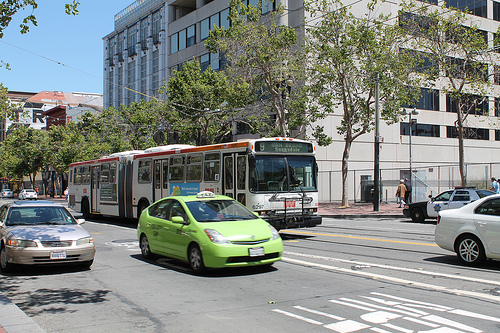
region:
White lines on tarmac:
[334, 293, 450, 326]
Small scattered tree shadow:
[22, 284, 119, 316]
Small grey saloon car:
[2, 203, 99, 272]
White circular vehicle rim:
[453, 235, 483, 264]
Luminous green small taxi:
[158, 193, 285, 281]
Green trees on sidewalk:
[102, 92, 204, 141]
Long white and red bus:
[94, 158, 259, 189]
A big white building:
[391, 128, 459, 165]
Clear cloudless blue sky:
[62, 26, 93, 53]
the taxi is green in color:
[132, 185, 316, 285]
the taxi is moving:
[164, 192, 268, 285]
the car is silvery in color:
[12, 185, 81, 280]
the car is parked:
[10, 185, 97, 290]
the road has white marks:
[344, 282, 425, 331]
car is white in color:
[438, 199, 499, 254]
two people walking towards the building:
[379, 165, 415, 198]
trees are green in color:
[86, 109, 184, 139]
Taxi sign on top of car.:
[199, 186, 218, 202]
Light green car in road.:
[134, 188, 259, 285]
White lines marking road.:
[331, 296, 379, 329]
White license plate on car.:
[246, 247, 266, 254]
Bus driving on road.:
[146, 156, 314, 202]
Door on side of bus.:
[90, 168, 110, 206]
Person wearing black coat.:
[406, 180, 416, 199]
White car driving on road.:
[438, 198, 489, 249]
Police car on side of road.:
[408, 190, 463, 224]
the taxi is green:
[144, 185, 282, 272]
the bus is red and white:
[132, 147, 321, 232]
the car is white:
[435, 201, 498, 268]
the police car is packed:
[401, 186, 481, 216]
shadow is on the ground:
[36, 285, 106, 322]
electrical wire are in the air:
[66, 61, 148, 101]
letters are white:
[315, 275, 460, 332]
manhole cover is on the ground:
[117, 234, 139, 254]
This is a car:
[136, 187, 288, 293]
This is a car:
[428, 191, 490, 241]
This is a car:
[400, 183, 497, 218]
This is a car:
[20, 180, 41, 210]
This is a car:
[2, 175, 27, 211]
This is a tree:
[427, 11, 497, 228]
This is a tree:
[312, 1, 380, 222]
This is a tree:
[230, 18, 312, 174]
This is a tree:
[171, 60, 243, 170]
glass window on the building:
[401, 120, 438, 136]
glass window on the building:
[398, 85, 439, 105]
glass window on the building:
[396, 8, 437, 41]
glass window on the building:
[445, 20, 485, 45]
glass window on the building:
[440, 55, 486, 78]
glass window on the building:
[445, 88, 486, 113]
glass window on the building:
[445, 128, 490, 141]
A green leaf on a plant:
[190, 79, 195, 81]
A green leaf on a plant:
[146, 109, 151, 113]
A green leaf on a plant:
[74, 145, 77, 146]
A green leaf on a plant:
[83, 148, 90, 152]